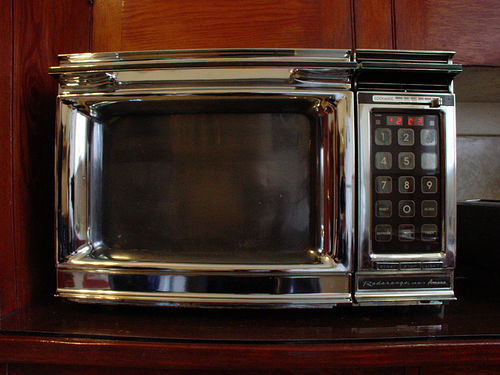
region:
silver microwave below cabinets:
[30, 35, 476, 353]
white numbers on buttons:
[373, 130, 436, 217]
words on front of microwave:
[352, 268, 449, 297]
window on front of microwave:
[102, 107, 317, 257]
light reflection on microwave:
[68, 98, 91, 188]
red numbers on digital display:
[385, 110, 428, 128]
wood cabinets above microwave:
[258, 25, 440, 58]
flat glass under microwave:
[134, 289, 346, 349]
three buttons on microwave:
[365, 258, 450, 275]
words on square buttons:
[421, 200, 440, 242]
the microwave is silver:
[174, 147, 308, 339]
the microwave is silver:
[136, 162, 248, 364]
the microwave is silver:
[187, 248, 268, 363]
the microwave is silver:
[142, 62, 328, 365]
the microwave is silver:
[213, 212, 388, 359]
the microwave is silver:
[215, 237, 317, 359]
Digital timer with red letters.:
[386, 115, 425, 127]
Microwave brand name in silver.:
[360, 279, 448, 286]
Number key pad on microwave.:
[373, 128, 441, 221]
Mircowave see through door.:
[106, 120, 308, 250]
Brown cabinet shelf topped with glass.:
[15, 316, 405, 356]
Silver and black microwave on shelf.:
[48, 52, 463, 315]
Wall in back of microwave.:
[465, 92, 499, 189]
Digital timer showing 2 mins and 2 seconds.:
[385, 116, 425, 128]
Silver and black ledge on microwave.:
[43, 59, 356, 76]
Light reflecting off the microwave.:
[52, 71, 104, 193]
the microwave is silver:
[160, 220, 253, 289]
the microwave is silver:
[256, 259, 332, 365]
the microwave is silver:
[200, 192, 292, 368]